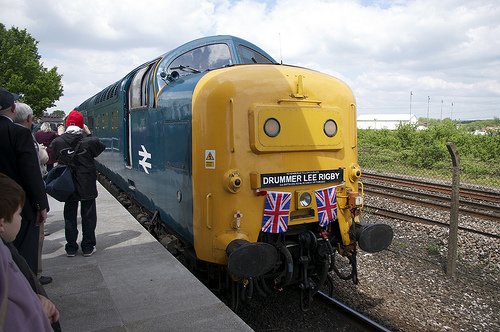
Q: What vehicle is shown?
A: A train.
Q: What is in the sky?
A: Clouds.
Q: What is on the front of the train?
A: Speakers.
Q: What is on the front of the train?
A: Flags.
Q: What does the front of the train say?
A: Drummer Lee Rigby.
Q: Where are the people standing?
A: On the sidewalk.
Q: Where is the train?
A: On the tracks.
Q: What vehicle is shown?
A: Train.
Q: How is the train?
A: Parked.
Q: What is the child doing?
A: Watching the train.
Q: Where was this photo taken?
A: A railway.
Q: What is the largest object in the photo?
A: A train.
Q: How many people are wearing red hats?
A: One.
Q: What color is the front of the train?
A: Yellow.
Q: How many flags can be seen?
A: Two.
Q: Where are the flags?
A: The front of the train.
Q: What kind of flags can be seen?
A: Union.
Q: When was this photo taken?
A: Daytime.